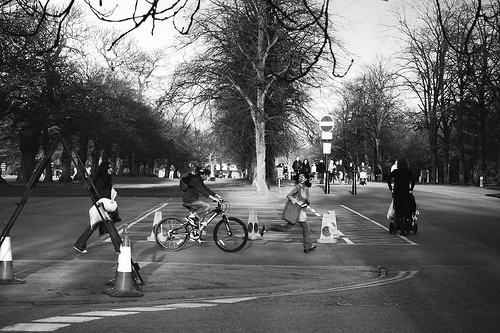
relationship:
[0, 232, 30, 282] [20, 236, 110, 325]
safety cone in street